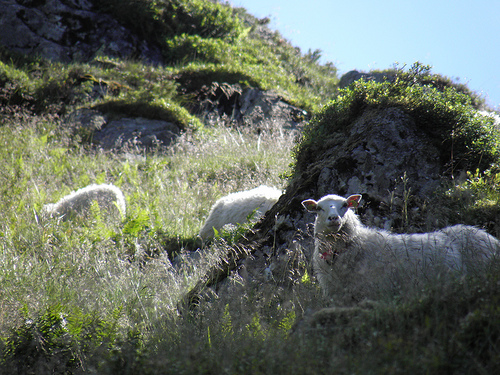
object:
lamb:
[296, 194, 499, 316]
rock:
[189, 102, 457, 303]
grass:
[4, 136, 74, 189]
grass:
[347, 80, 406, 109]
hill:
[0, 1, 499, 141]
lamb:
[39, 178, 126, 238]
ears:
[300, 199, 321, 212]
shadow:
[160, 236, 204, 258]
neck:
[196, 208, 218, 250]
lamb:
[196, 185, 281, 255]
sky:
[326, 1, 498, 60]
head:
[301, 194, 363, 237]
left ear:
[299, 197, 318, 215]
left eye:
[316, 206, 323, 214]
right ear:
[347, 193, 363, 207]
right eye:
[341, 204, 348, 210]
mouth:
[327, 222, 341, 231]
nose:
[326, 215, 340, 222]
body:
[312, 223, 497, 304]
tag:
[351, 200, 358, 206]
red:
[320, 253, 326, 259]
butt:
[103, 182, 124, 203]